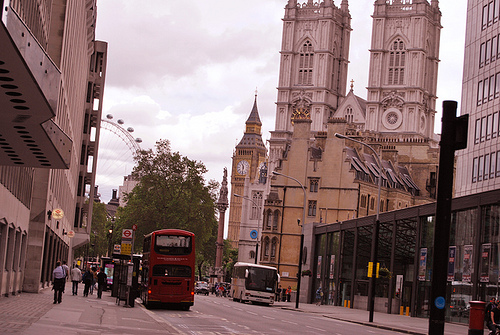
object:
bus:
[139, 227, 198, 308]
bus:
[228, 260, 287, 305]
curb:
[268, 298, 307, 313]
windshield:
[246, 266, 279, 293]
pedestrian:
[49, 260, 71, 305]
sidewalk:
[2, 281, 189, 335]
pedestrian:
[95, 265, 111, 299]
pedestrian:
[69, 261, 87, 296]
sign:
[366, 261, 374, 279]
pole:
[366, 219, 381, 321]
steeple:
[349, 75, 356, 89]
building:
[444, 0, 500, 321]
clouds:
[93, 1, 269, 88]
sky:
[79, 0, 470, 236]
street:
[135, 291, 427, 335]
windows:
[472, 155, 477, 183]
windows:
[473, 116, 483, 145]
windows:
[476, 77, 483, 108]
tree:
[110, 162, 223, 291]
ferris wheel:
[81, 110, 162, 244]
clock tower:
[228, 87, 272, 266]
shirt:
[51, 265, 74, 282]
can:
[466, 300, 490, 334]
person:
[287, 284, 294, 302]